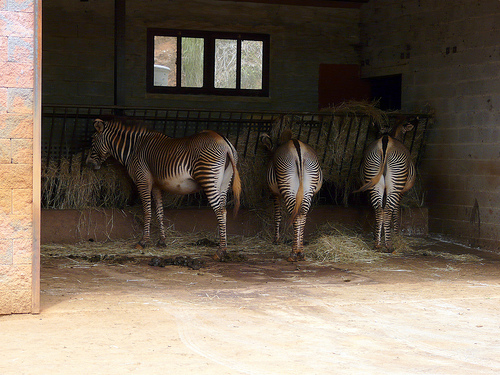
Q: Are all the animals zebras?
A: Yes, all the animals are zebras.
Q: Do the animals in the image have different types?
A: No, all the animals are zebras.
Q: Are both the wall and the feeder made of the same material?
A: No, the wall is made of cement and the feeder is made of metal.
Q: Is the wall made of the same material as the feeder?
A: No, the wall is made of cement and the feeder is made of metal.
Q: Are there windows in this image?
A: Yes, there is a window.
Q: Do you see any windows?
A: Yes, there is a window.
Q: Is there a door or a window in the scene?
A: Yes, there is a window.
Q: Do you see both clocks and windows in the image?
A: No, there is a window but no clocks.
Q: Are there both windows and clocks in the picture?
A: No, there is a window but no clocks.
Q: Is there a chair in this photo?
A: No, there are no chairs.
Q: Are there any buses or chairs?
A: No, there are no chairs or buses.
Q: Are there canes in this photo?
A: No, there are no canes.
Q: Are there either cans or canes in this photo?
A: No, there are no canes or cans.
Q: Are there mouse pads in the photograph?
A: No, there are no mouse pads.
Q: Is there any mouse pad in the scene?
A: No, there are no mouse pads.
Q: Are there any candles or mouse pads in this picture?
A: No, there are no mouse pads or candles.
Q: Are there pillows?
A: No, there are no pillows.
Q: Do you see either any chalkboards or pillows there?
A: No, there are no pillows or chalkboards.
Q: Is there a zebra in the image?
A: Yes, there is a zebra.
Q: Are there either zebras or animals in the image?
A: Yes, there is a zebra.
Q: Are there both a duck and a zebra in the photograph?
A: No, there is a zebra but no ducks.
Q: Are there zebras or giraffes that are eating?
A: Yes, the zebra is eating.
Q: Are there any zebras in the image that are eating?
A: Yes, there is a zebra that is eating.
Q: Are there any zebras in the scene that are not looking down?
A: Yes, there is a zebra that is eating.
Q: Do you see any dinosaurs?
A: No, there are no dinosaurs.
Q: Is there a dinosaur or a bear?
A: No, there are no dinosaurs or bears.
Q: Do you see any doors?
A: Yes, there is a door.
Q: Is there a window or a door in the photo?
A: Yes, there is a door.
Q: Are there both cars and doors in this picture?
A: No, there is a door but no cars.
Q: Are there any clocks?
A: No, there are no clocks.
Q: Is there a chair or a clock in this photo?
A: No, there are no clocks or chairs.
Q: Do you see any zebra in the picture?
A: Yes, there is a zebra.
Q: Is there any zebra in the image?
A: Yes, there is a zebra.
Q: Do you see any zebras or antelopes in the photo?
A: Yes, there is a zebra.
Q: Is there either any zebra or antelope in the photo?
A: Yes, there is a zebra.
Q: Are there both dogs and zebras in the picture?
A: No, there is a zebra but no dogs.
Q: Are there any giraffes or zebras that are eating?
A: Yes, the zebra is eating.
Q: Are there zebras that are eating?
A: Yes, there is a zebra that is eating.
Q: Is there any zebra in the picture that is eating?
A: Yes, there is a zebra that is eating.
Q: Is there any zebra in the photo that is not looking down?
A: Yes, there is a zebra that is eating.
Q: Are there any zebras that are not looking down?
A: Yes, there is a zebra that is eating.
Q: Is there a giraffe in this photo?
A: No, there are no giraffes.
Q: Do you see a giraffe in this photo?
A: No, there are no giraffes.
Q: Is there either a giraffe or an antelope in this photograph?
A: No, there are no giraffes or antelopes.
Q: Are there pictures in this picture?
A: No, there are no pictures.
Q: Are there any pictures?
A: No, there are no pictures.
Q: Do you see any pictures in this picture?
A: No, there are no pictures.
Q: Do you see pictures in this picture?
A: No, there are no pictures.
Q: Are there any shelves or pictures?
A: No, there are no pictures or shelves.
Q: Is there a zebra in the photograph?
A: Yes, there is a zebra.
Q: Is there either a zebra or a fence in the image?
A: Yes, there is a zebra.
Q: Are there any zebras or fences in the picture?
A: Yes, there is a zebra.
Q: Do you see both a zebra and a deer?
A: No, there is a zebra but no deer.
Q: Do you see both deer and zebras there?
A: No, there is a zebra but no deer.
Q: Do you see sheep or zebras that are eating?
A: Yes, the zebra is eating.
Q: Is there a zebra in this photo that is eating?
A: Yes, there is a zebra that is eating.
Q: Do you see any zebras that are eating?
A: Yes, there is a zebra that is eating.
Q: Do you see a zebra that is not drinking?
A: Yes, there is a zebra that is eating .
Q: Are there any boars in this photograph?
A: No, there are no boars.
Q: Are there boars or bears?
A: No, there are no boars or bears.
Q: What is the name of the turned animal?
A: The animal is a zebra.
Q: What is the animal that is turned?
A: The animal is a zebra.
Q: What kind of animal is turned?
A: The animal is a zebra.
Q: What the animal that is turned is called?
A: The animal is a zebra.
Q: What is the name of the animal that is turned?
A: The animal is a zebra.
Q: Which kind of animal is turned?
A: The animal is a zebra.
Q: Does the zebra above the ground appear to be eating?
A: Yes, the zebra is eating.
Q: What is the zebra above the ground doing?
A: The zebra is eating.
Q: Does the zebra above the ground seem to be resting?
A: No, the zebra is eating.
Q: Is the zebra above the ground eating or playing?
A: The zebra is eating.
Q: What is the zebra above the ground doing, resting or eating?
A: The zebra is eating.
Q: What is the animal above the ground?
A: The animal is a zebra.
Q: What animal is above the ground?
A: The animal is a zebra.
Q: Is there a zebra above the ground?
A: Yes, there is a zebra above the ground.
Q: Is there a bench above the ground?
A: No, there is a zebra above the ground.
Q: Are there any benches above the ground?
A: No, there is a zebra above the ground.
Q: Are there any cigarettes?
A: No, there are no cigarettes.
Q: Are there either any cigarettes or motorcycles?
A: No, there are no cigarettes or motorcycles.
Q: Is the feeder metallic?
A: Yes, the feeder is metallic.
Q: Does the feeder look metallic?
A: Yes, the feeder is metallic.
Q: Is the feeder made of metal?
A: Yes, the feeder is made of metal.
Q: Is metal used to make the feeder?
A: Yes, the feeder is made of metal.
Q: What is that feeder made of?
A: The feeder is made of metal.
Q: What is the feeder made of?
A: The feeder is made of metal.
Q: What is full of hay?
A: The feeder is full of hay.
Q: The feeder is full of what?
A: The feeder is full of hay.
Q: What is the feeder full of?
A: The feeder is full of hay.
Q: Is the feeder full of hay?
A: Yes, the feeder is full of hay.